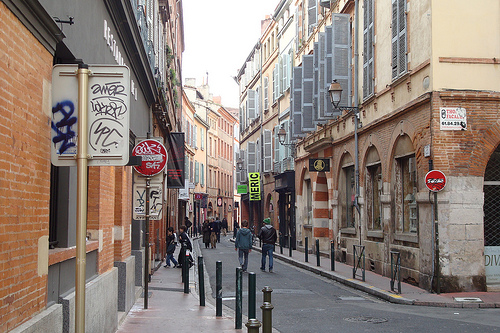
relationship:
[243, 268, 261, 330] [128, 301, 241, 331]
green post in pavement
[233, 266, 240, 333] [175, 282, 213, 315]
pole in pavement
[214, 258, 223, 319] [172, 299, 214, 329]
pole in pavement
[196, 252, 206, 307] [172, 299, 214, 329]
pole in pavement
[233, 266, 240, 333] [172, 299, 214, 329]
pole in pavement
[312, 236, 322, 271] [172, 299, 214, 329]
post in pavement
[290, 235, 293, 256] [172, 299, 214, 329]
post in pavement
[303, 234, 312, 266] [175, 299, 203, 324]
post in pavement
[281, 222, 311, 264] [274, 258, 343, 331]
post in pavement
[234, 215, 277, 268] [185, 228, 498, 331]
males on pavement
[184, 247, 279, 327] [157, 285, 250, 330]
poles on sidewalk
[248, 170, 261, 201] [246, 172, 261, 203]
sign on sign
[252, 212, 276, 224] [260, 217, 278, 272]
hat on men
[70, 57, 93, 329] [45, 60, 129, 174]
pole holding sign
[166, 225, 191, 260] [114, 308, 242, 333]
people on pavement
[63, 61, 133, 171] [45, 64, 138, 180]
graffiti on sign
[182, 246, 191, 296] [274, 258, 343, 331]
post line pavement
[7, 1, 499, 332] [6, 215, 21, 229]
buildings ofq brick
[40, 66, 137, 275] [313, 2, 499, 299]
windows in building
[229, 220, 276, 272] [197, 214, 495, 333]
men in street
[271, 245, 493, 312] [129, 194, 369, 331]
curb on a sidewalk